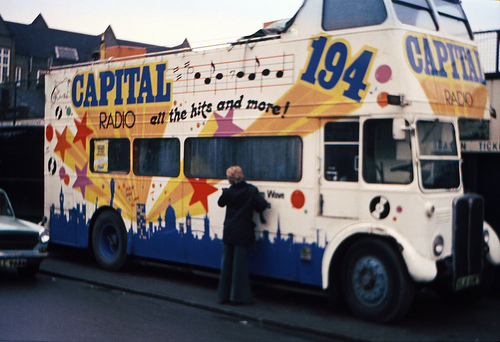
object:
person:
[217, 165, 273, 306]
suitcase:
[105, 46, 147, 61]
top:
[42, 0, 500, 72]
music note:
[186, 66, 194, 93]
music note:
[204, 59, 216, 85]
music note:
[236, 70, 245, 79]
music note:
[261, 69, 270, 77]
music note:
[64, 79, 70, 99]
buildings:
[47, 177, 328, 289]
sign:
[98, 110, 137, 130]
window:
[184, 135, 304, 182]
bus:
[41, 0, 500, 326]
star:
[185, 178, 218, 213]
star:
[71, 161, 93, 200]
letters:
[71, 63, 171, 108]